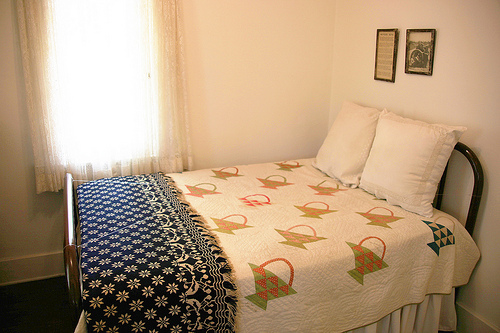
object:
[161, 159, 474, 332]
quilt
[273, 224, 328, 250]
basket pattern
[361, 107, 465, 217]
pillow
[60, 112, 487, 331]
bed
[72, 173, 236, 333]
blanket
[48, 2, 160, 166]
sunlight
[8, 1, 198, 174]
window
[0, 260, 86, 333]
part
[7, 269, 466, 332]
bedroom floor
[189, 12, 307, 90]
part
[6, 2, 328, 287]
bedroom wall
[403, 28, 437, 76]
picture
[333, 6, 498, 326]
wall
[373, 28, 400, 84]
picture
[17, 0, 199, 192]
curtains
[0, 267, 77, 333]
carpet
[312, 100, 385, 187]
pillows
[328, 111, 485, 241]
frame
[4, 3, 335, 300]
walls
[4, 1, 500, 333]
room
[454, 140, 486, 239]
metal post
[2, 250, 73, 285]
trim